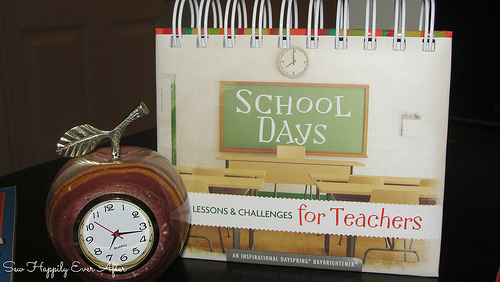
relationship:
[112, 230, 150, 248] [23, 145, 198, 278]
hand on a clock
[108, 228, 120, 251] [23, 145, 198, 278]
hand on a clock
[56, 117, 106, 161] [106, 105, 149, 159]
leaf and stem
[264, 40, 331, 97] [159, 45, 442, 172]
clock hanging on wall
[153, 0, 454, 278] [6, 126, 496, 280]
calendar on desk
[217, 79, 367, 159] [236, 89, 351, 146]
chalkboard with writing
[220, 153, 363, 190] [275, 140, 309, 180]
desk and chair